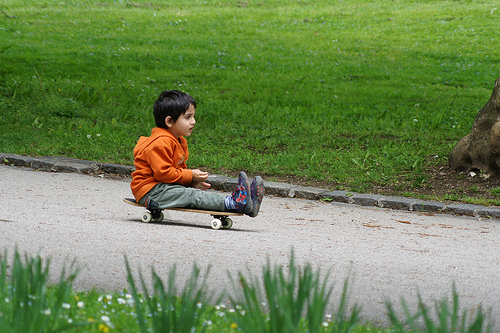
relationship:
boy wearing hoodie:
[130, 89, 265, 217] [131, 127, 193, 204]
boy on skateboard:
[130, 89, 265, 217] [117, 197, 246, 232]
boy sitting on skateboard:
[130, 89, 265, 217] [119, 191, 251, 234]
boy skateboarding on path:
[130, 89, 265, 217] [19, 166, 499, 311]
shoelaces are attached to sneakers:
[226, 183, 246, 204] [235, 161, 266, 220]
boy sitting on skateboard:
[122, 81, 206, 190] [120, 193, 244, 232]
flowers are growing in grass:
[158, 10, 288, 83] [87, 11, 351, 68]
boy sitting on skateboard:
[130, 89, 265, 217] [120, 199, 253, 231]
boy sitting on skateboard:
[130, 89, 265, 217] [109, 188, 246, 226]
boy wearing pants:
[130, 89, 265, 217] [141, 175, 236, 205]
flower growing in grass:
[400, 107, 421, 128] [343, 95, 405, 153]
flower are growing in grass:
[411, 118, 420, 123] [398, 20, 472, 74]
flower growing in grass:
[71, 295, 91, 310] [46, 289, 160, 329]